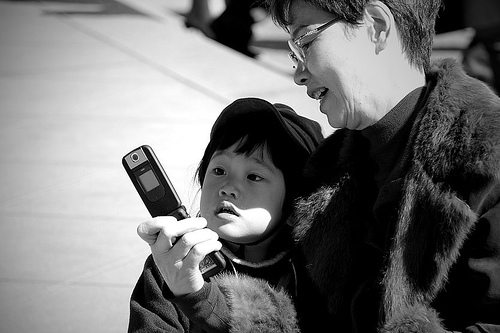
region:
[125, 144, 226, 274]
a cell phone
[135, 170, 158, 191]
the screen on the cell phone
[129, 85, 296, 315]
a young girl looking at a cell phone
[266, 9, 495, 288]
a lady wearing a fur coat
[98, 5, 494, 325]
a lady holding a cell phone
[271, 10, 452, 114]
a lady wearing glasses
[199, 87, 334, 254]
a young child wearing a hat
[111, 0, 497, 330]
two people looking at a cell phone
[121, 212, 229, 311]
the hand of the lady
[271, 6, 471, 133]
a smiling lady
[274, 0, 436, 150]
An Asian lady wearing glasses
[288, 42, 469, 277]
The lady is wearing a fur coat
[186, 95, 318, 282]
a young child in a hat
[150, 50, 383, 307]
The lady is holding a cell phone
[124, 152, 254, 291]
The child is looking at the phone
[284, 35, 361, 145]
The lady is talking and explaining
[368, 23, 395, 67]
The lady is not wearing earrings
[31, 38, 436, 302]
The photo is in black and white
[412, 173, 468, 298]
The coat is made with fur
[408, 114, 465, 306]
The fur is dark in color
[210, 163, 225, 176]
the dark eye on the face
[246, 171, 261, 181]
the dark eye on the face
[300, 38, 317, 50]
the dark eye on the face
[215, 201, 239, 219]
the mouth on the face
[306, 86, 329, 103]
the mouth on the face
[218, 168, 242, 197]
the nose on the face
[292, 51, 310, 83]
the nose on the face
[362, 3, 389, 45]
the ear on the head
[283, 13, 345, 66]
the black framed glasses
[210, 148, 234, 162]
the dark eyebrow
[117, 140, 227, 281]
black and silver plastic cell phone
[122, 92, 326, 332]
little boy looking at a cell phone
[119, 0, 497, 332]
lady holding a cell phone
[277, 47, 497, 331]
fur covered lapel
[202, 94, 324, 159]
black hat with brim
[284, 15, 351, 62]
round wire framed glasses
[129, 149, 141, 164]
small phone camera lens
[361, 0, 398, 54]
lady's left ear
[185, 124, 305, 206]
kids shaggy black hair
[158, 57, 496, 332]
woamn's fur trimmed coat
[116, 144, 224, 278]
cell phone in woman's hand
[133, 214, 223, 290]
the woman's right hand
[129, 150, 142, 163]
the camera on the phone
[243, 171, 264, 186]
left eye on the kid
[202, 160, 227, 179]
right eye on the kid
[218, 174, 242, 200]
the nose on the kid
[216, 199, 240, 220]
the mouth on the kid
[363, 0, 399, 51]
left ear on the woman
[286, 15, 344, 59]
glasses on the woman's face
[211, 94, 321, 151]
hat on the kid's head